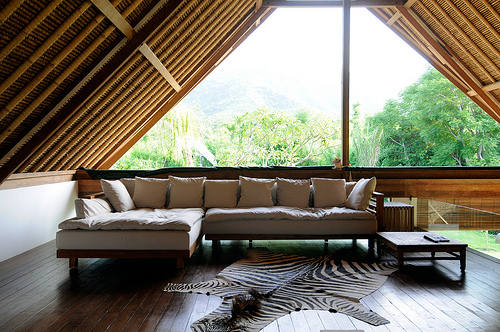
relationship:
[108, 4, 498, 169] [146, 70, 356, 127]
window in mountains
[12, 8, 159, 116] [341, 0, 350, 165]
roof open beam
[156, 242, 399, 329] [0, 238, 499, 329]
rug on a floor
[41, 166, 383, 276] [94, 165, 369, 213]
sofa with many pillows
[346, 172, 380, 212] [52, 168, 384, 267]
pillow at end of sofa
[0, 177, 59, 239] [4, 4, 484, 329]
wall to side of room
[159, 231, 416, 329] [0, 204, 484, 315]
skin on floor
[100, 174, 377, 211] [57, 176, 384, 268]
cushions on couch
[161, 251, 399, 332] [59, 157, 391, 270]
rug in front of sofa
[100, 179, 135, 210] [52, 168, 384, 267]
pillow on sofa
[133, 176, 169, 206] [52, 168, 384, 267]
pillow on sofa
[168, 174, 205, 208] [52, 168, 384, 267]
pillow on sofa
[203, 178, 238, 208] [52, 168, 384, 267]
pillow on sofa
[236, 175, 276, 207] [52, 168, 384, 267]
pillow on sofa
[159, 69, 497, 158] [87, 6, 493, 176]
trees outside window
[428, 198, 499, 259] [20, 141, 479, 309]
glass railing next to sitting area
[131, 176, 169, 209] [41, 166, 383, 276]
pillow along back of sofa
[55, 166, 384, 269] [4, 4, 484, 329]
sofa in room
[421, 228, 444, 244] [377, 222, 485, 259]
remotes on table